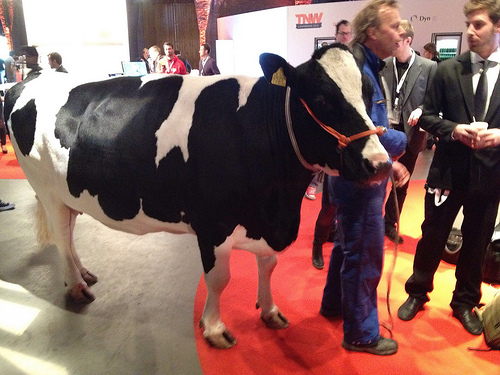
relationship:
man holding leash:
[317, 0, 411, 355] [370, 126, 403, 331]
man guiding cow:
[317, 0, 411, 355] [10, 40, 405, 351]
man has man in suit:
[395, 0, 499, 336] [402, 48, 500, 311]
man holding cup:
[395, 0, 499, 336] [463, 107, 484, 150]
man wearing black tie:
[407, 4, 482, 334] [465, 46, 497, 151]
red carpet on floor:
[185, 257, 458, 373] [24, 86, 484, 356]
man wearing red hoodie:
[150, 40, 199, 84] [162, 51, 200, 81]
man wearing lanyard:
[367, 12, 437, 239] [382, 51, 423, 116]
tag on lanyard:
[387, 96, 399, 125] [382, 51, 423, 116]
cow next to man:
[10, 40, 405, 351] [330, 1, 407, 355]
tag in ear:
[266, 63, 292, 92] [252, 41, 292, 86]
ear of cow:
[252, 41, 292, 86] [10, 40, 405, 351]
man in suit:
[407, 4, 482, 334] [403, 44, 484, 302]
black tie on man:
[472, 59, 492, 122] [404, 12, 484, 294]